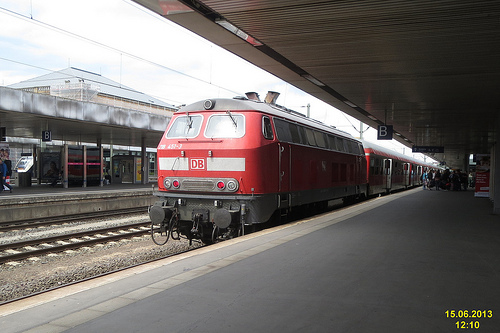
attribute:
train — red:
[156, 90, 424, 240]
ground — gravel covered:
[0, 209, 218, 306]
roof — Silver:
[121, 0, 498, 180]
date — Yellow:
[444, 309, 492, 318]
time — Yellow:
[453, 320, 479, 329]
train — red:
[179, 91, 391, 202]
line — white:
[156, 153, 247, 173]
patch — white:
[159, 157, 188, 169]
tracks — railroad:
[2, 212, 137, 268]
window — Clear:
[67, 145, 82, 158]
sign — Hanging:
[375, 121, 395, 143]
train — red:
[135, 87, 460, 249]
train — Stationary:
[157, 96, 447, 231]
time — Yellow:
[451, 315, 484, 331]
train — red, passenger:
[146, 90, 446, 247]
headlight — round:
[163, 178, 171, 188]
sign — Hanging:
[409, 132, 451, 159]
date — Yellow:
[445, 310, 493, 317]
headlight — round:
[164, 170, 239, 192]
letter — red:
[187, 152, 205, 174]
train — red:
[100, 87, 431, 236]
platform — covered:
[286, 198, 476, 320]